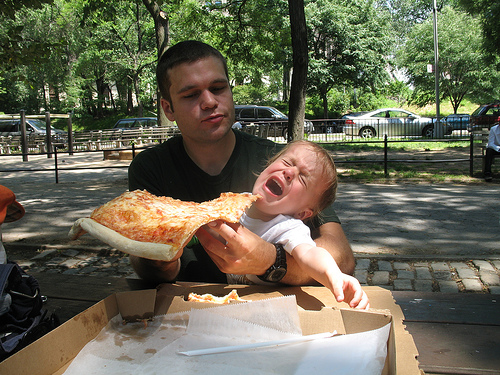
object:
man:
[126, 38, 357, 288]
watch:
[254, 243, 290, 285]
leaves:
[80, 22, 130, 52]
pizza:
[65, 188, 263, 263]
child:
[202, 138, 370, 312]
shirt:
[128, 130, 344, 285]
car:
[343, 107, 453, 139]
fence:
[0, 113, 471, 157]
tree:
[288, 0, 311, 145]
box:
[0, 280, 428, 374]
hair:
[156, 37, 232, 114]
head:
[155, 38, 236, 144]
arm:
[281, 220, 342, 287]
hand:
[191, 221, 280, 276]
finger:
[207, 220, 242, 249]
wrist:
[273, 245, 289, 285]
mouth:
[199, 110, 226, 128]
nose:
[199, 87, 219, 111]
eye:
[178, 92, 200, 101]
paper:
[59, 292, 305, 374]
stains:
[142, 348, 160, 355]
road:
[266, 130, 471, 144]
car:
[0, 117, 65, 148]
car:
[112, 117, 178, 146]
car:
[230, 104, 314, 140]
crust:
[65, 190, 263, 264]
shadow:
[0, 141, 499, 374]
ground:
[0, 129, 499, 374]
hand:
[324, 270, 372, 310]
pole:
[19, 109, 28, 162]